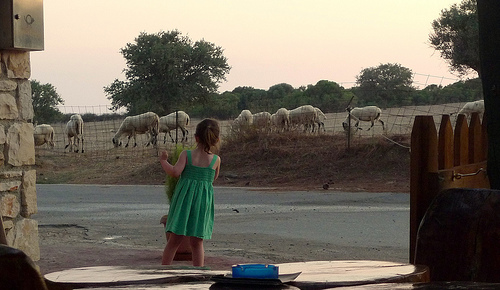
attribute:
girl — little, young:
[157, 115, 224, 267]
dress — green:
[164, 150, 217, 245]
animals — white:
[106, 113, 192, 149]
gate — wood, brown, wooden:
[400, 114, 491, 263]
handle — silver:
[451, 167, 489, 180]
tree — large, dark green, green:
[107, 22, 233, 127]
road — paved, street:
[33, 183, 416, 252]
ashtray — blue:
[228, 258, 283, 279]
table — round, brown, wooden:
[42, 259, 434, 286]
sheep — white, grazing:
[230, 107, 337, 134]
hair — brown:
[198, 117, 221, 153]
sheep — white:
[108, 108, 192, 145]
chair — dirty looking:
[409, 184, 499, 288]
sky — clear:
[28, 2, 482, 87]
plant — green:
[159, 148, 184, 209]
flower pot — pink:
[158, 216, 198, 264]